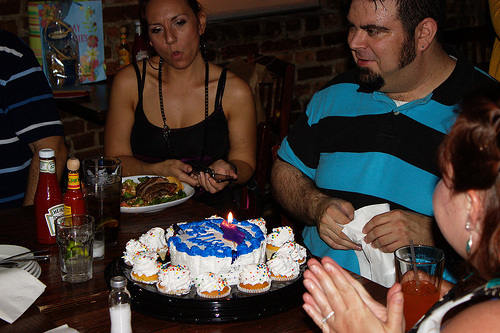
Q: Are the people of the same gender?
A: No, they are both male and female.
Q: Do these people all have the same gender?
A: No, they are both male and female.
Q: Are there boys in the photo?
A: No, there are no boys.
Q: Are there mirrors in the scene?
A: No, there are no mirrors.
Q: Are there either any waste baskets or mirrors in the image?
A: No, there are no mirrors or waste baskets.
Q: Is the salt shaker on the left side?
A: Yes, the salt shaker is on the left of the image.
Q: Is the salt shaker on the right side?
A: No, the salt shaker is on the left of the image.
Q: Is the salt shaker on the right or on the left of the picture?
A: The salt shaker is on the left of the image.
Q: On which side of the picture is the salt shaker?
A: The salt shaker is on the left of the image.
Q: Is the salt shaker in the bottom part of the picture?
A: Yes, the salt shaker is in the bottom of the image.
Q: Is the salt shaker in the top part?
A: No, the salt shaker is in the bottom of the image.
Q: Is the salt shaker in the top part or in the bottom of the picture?
A: The salt shaker is in the bottom of the image.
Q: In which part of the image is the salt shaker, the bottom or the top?
A: The salt shaker is in the bottom of the image.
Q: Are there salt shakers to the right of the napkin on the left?
A: Yes, there is a salt shaker to the right of the napkin.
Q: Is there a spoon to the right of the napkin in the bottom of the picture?
A: No, there is a salt shaker to the right of the napkin.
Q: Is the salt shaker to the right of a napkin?
A: Yes, the salt shaker is to the right of a napkin.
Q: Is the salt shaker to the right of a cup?
A: No, the salt shaker is to the right of a napkin.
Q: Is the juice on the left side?
A: Yes, the juice is on the left of the image.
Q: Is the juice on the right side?
A: No, the juice is on the left of the image.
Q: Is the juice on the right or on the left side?
A: The juice is on the left of the image.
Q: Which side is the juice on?
A: The juice is on the left of the image.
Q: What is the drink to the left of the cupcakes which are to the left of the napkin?
A: The drink is juice.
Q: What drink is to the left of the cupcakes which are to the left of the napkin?
A: The drink is juice.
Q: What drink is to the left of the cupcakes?
A: The drink is juice.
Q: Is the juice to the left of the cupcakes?
A: Yes, the juice is to the left of the cupcakes.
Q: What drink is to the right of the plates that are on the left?
A: The drink is juice.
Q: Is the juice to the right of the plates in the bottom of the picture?
A: Yes, the juice is to the right of the plates.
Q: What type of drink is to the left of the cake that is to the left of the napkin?
A: The drink is juice.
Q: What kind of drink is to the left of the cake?
A: The drink is juice.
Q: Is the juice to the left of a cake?
A: Yes, the juice is to the left of a cake.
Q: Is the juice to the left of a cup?
A: No, the juice is to the left of a cake.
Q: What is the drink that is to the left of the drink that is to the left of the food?
A: The drink is juice.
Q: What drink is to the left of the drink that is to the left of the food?
A: The drink is juice.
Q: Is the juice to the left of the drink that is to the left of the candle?
A: Yes, the juice is to the left of the drink.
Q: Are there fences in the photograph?
A: No, there are no fences.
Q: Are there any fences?
A: No, there are no fences.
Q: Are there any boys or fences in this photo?
A: No, there are no fences or boys.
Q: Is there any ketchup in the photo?
A: Yes, there is ketchup.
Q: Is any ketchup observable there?
A: Yes, there is ketchup.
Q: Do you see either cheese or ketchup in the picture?
A: Yes, there is ketchup.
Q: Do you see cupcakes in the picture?
A: Yes, there are cupcakes.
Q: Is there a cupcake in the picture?
A: Yes, there are cupcakes.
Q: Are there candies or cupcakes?
A: Yes, there are cupcakes.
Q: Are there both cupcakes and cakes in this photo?
A: Yes, there are both cupcakes and a cake.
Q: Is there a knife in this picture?
A: No, there are no knives.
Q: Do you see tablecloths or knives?
A: No, there are no knives or tablecloths.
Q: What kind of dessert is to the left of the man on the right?
A: The dessert is cupcakes.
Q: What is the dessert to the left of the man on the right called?
A: The dessert is cupcakes.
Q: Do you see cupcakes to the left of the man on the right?
A: Yes, there are cupcakes to the left of the man.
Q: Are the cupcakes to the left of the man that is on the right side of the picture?
A: Yes, the cupcakes are to the left of the man.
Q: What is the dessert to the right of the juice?
A: The dessert is cupcakes.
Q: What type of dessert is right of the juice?
A: The dessert is cupcakes.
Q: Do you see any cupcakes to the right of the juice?
A: Yes, there are cupcakes to the right of the juice.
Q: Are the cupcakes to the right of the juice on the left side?
A: Yes, the cupcakes are to the right of the juice.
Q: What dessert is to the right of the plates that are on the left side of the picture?
A: The dessert is cupcakes.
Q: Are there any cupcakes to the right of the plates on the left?
A: Yes, there are cupcakes to the right of the plates.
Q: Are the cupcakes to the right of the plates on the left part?
A: Yes, the cupcakes are to the right of the plates.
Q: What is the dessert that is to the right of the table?
A: The dessert is cupcakes.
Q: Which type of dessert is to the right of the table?
A: The dessert is cupcakes.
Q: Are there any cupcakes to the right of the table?
A: Yes, there are cupcakes to the right of the table.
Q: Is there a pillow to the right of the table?
A: No, there are cupcakes to the right of the table.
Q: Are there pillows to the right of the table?
A: No, there are cupcakes to the right of the table.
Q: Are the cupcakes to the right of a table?
A: Yes, the cupcakes are to the right of a table.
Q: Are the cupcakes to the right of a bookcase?
A: No, the cupcakes are to the right of a table.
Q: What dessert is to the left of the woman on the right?
A: The dessert is cupcakes.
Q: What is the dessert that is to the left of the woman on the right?
A: The dessert is cupcakes.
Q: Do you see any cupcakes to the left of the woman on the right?
A: Yes, there are cupcakes to the left of the woman.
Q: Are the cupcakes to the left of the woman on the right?
A: Yes, the cupcakes are to the left of the woman.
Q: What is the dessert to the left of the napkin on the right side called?
A: The dessert is cupcakes.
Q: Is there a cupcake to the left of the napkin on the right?
A: Yes, there are cupcakes to the left of the napkin.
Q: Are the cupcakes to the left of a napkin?
A: Yes, the cupcakes are to the left of a napkin.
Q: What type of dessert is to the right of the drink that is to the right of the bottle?
A: The dessert is cupcakes.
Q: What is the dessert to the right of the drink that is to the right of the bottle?
A: The dessert is cupcakes.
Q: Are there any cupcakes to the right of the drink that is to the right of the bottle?
A: Yes, there are cupcakes to the right of the drink.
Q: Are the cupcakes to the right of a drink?
A: Yes, the cupcakes are to the right of a drink.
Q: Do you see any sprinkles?
A: Yes, there are sprinkles.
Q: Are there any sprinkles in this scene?
A: Yes, there are sprinkles.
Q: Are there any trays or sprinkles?
A: Yes, there are sprinkles.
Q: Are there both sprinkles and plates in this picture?
A: Yes, there are both sprinkles and a plate.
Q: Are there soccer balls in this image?
A: No, there are no soccer balls.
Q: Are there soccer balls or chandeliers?
A: No, there are no soccer balls or chandeliers.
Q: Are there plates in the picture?
A: Yes, there is a plate.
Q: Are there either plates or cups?
A: Yes, there is a plate.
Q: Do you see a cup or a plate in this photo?
A: Yes, there is a plate.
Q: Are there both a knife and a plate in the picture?
A: No, there is a plate but no knives.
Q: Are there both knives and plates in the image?
A: No, there is a plate but no knives.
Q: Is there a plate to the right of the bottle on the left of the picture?
A: Yes, there is a plate to the right of the bottle.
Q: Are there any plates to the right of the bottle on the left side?
A: Yes, there is a plate to the right of the bottle.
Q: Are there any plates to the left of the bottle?
A: No, the plate is to the right of the bottle.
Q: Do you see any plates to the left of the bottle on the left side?
A: No, the plate is to the right of the bottle.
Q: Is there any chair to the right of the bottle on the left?
A: No, there is a plate to the right of the bottle.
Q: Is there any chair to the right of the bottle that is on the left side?
A: No, there is a plate to the right of the bottle.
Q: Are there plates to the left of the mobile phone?
A: Yes, there is a plate to the left of the mobile phone.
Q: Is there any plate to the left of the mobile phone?
A: Yes, there is a plate to the left of the mobile phone.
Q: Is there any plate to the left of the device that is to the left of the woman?
A: Yes, there is a plate to the left of the mobile phone.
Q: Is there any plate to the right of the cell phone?
A: No, the plate is to the left of the cell phone.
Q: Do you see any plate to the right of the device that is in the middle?
A: No, the plate is to the left of the cell phone.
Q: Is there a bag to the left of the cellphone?
A: No, there is a plate to the left of the cellphone.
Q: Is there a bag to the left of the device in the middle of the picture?
A: No, there is a plate to the left of the cellphone.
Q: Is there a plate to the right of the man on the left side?
A: Yes, there is a plate to the right of the man.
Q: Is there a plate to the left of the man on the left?
A: No, the plate is to the right of the man.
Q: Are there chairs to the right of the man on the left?
A: No, there is a plate to the right of the man.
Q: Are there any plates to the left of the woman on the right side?
A: Yes, there is a plate to the left of the woman.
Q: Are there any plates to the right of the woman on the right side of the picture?
A: No, the plate is to the left of the woman.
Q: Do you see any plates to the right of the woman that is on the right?
A: No, the plate is to the left of the woman.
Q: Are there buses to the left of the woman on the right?
A: No, there is a plate to the left of the woman.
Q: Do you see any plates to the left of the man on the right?
A: Yes, there is a plate to the left of the man.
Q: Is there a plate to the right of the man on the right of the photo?
A: No, the plate is to the left of the man.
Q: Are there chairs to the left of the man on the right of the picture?
A: No, there is a plate to the left of the man.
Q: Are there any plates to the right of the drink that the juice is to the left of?
A: Yes, there is a plate to the right of the drink.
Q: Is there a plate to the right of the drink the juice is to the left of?
A: Yes, there is a plate to the right of the drink.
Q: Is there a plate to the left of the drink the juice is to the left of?
A: No, the plate is to the right of the drink.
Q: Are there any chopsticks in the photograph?
A: No, there are no chopsticks.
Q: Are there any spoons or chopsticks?
A: No, there are no chopsticks or spoons.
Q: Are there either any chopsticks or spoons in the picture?
A: No, there are no chopsticks or spoons.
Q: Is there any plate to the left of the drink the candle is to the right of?
A: Yes, there are plates to the left of the drink.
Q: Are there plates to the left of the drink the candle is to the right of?
A: Yes, there are plates to the left of the drink.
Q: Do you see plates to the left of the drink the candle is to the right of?
A: Yes, there are plates to the left of the drink.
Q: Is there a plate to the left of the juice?
A: Yes, there are plates to the left of the juice.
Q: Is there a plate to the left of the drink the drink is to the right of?
A: Yes, there are plates to the left of the juice.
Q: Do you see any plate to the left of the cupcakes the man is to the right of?
A: Yes, there are plates to the left of the cupcakes.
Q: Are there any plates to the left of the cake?
A: Yes, there are plates to the left of the cake.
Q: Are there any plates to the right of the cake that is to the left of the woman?
A: No, the plates are to the left of the cake.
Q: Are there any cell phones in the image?
A: Yes, there is a cell phone.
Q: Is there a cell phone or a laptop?
A: Yes, there is a cell phone.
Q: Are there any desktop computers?
A: No, there are no desktop computers.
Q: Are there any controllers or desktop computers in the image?
A: No, there are no desktop computers or controllers.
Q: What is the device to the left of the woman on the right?
A: The device is a cell phone.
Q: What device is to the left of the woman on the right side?
A: The device is a cell phone.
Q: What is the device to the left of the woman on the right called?
A: The device is a cell phone.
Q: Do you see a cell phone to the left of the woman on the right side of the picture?
A: Yes, there is a cell phone to the left of the woman.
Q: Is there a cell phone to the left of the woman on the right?
A: Yes, there is a cell phone to the left of the woman.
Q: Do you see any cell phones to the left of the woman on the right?
A: Yes, there is a cell phone to the left of the woman.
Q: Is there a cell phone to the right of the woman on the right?
A: No, the cell phone is to the left of the woman.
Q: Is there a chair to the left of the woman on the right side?
A: No, there is a cell phone to the left of the woman.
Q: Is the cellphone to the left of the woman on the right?
A: Yes, the cellphone is to the left of the woman.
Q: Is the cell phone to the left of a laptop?
A: No, the cell phone is to the left of the woman.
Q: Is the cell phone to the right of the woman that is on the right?
A: No, the cell phone is to the left of the woman.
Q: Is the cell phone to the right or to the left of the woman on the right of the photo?
A: The cell phone is to the left of the woman.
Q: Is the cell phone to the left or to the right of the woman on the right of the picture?
A: The cell phone is to the left of the woman.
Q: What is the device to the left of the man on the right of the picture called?
A: The device is a cell phone.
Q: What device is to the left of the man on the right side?
A: The device is a cell phone.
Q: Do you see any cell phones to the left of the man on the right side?
A: Yes, there is a cell phone to the left of the man.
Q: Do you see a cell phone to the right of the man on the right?
A: No, the cell phone is to the left of the man.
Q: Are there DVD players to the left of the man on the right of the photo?
A: No, there is a cell phone to the left of the man.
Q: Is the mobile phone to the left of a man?
A: Yes, the mobile phone is to the left of a man.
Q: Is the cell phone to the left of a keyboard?
A: No, the cell phone is to the left of a man.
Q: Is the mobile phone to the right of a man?
A: No, the mobile phone is to the left of a man.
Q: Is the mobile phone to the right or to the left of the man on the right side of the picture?
A: The mobile phone is to the left of the man.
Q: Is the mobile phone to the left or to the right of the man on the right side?
A: The mobile phone is to the left of the man.